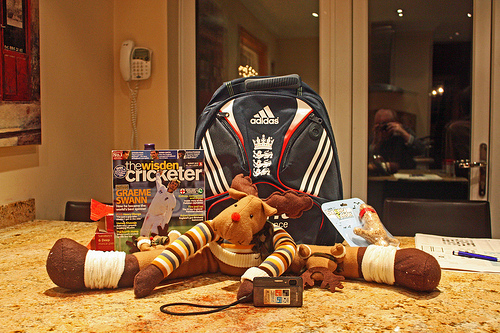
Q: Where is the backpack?
A: On the counter.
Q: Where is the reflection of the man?
A: On the door.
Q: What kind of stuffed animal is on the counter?
A: A reindeer.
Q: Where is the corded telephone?
A: On the wall.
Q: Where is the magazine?
A: Next to the backpack.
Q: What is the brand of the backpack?
A: Adidas.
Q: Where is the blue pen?
A: On the white paper.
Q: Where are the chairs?
A: Front of the counter.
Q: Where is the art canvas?
A: On the wall.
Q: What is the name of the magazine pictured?
A: The Wisden Cricketer.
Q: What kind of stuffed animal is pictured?
A: Reindeer.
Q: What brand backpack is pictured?
A: Adidas.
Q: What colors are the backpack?
A: Black, white, and red.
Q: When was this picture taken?
A: Nighttime.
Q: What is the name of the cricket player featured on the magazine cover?
A: Graeme Swann.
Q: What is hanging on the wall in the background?
A: A phone.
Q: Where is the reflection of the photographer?
A: In the glass door.